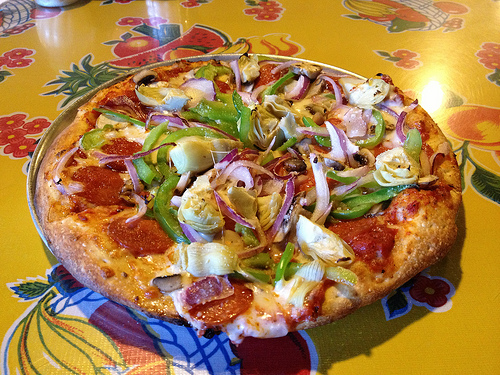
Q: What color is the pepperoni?
A: Red.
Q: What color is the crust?
A: Brown.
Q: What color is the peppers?
A: Green.